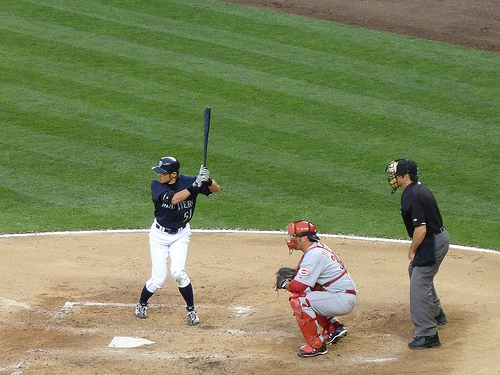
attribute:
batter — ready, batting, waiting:
[135, 156, 220, 324]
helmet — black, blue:
[151, 157, 180, 175]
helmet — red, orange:
[292, 220, 320, 240]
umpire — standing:
[386, 158, 450, 349]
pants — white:
[144, 217, 192, 294]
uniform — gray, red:
[288, 242, 356, 352]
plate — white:
[108, 335, 156, 348]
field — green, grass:
[0, 1, 499, 253]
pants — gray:
[410, 229, 451, 337]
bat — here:
[202, 108, 211, 168]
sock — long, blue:
[179, 284, 197, 306]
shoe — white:
[135, 301, 148, 319]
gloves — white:
[195, 165, 209, 187]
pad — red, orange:
[289, 291, 322, 353]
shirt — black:
[401, 182, 444, 239]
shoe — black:
[408, 332, 438, 348]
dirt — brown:
[217, 0, 500, 53]